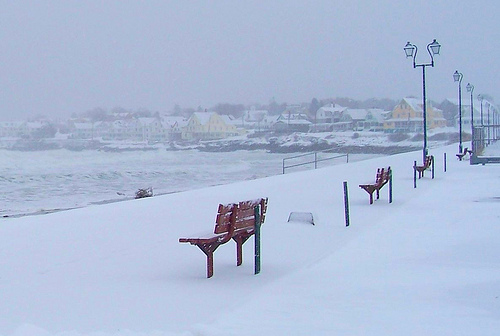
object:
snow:
[6, 218, 94, 335]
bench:
[179, 195, 271, 279]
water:
[0, 149, 398, 217]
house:
[382, 93, 447, 132]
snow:
[403, 96, 433, 113]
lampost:
[402, 39, 443, 166]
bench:
[411, 154, 436, 180]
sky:
[0, 0, 500, 119]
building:
[314, 101, 348, 133]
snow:
[181, 232, 225, 240]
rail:
[282, 145, 350, 175]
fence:
[468, 125, 500, 167]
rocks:
[262, 137, 383, 154]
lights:
[429, 38, 442, 57]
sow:
[10, 161, 174, 184]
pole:
[387, 165, 394, 204]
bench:
[358, 164, 394, 206]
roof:
[391, 97, 440, 114]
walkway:
[1, 141, 500, 336]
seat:
[177, 225, 257, 247]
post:
[458, 82, 463, 162]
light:
[452, 69, 462, 82]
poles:
[413, 160, 417, 189]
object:
[134, 186, 156, 203]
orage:
[383, 97, 448, 130]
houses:
[273, 112, 312, 133]